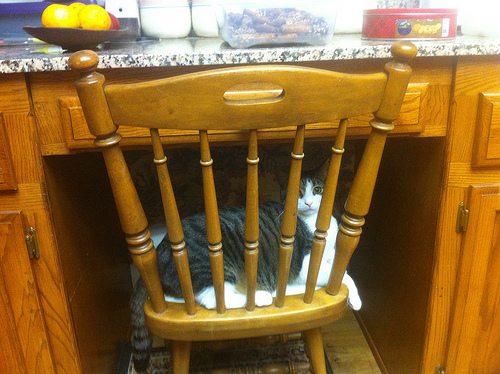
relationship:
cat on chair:
[118, 154, 363, 373] [68, 38, 418, 374]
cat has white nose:
[118, 154, 363, 373] [305, 197, 316, 208]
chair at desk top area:
[68, 38, 418, 374] [0, 32, 499, 159]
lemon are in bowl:
[42, 4, 79, 27] [20, 23, 131, 51]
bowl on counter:
[20, 23, 131, 51] [1, 5, 500, 74]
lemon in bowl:
[78, 4, 113, 32] [20, 23, 131, 51]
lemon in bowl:
[43, 1, 80, 27] [20, 23, 131, 51]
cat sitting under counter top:
[118, 154, 363, 373] [1, 5, 500, 74]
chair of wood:
[68, 38, 418, 374] [68, 40, 418, 373]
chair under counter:
[68, 38, 418, 374] [1, 5, 500, 74]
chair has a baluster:
[68, 38, 418, 374] [148, 126, 199, 316]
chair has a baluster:
[68, 38, 418, 374] [198, 129, 226, 315]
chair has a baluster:
[68, 38, 418, 374] [242, 127, 260, 311]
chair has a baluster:
[68, 38, 418, 374] [275, 125, 306, 308]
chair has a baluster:
[68, 38, 418, 374] [306, 120, 349, 304]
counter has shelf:
[1, 5, 500, 74] [0, 37, 499, 76]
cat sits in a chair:
[118, 154, 363, 373] [68, 38, 418, 374]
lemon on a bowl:
[42, 4, 79, 27] [20, 23, 131, 51]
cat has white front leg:
[118, 154, 363, 373] [337, 269, 364, 313]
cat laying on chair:
[118, 154, 363, 373] [68, 38, 418, 374]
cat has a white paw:
[118, 154, 363, 373] [337, 269, 364, 313]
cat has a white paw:
[118, 154, 363, 373] [199, 289, 275, 307]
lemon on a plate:
[78, 4, 113, 32] [20, 23, 131, 51]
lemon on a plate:
[43, 1, 80, 27] [20, 23, 131, 51]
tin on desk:
[360, 7, 459, 42] [1, 10, 499, 373]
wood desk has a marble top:
[1, 10, 499, 373] [1, 5, 500, 74]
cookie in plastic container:
[281, 22, 312, 36] [215, 4, 337, 49]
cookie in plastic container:
[257, 19, 281, 37] [215, 4, 337, 49]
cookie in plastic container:
[224, 11, 245, 32] [215, 4, 337, 49]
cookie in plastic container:
[259, 32, 297, 44] [215, 4, 337, 49]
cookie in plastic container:
[313, 17, 334, 42] [215, 4, 337, 49]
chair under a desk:
[68, 38, 418, 374] [1, 10, 499, 373]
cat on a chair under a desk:
[118, 154, 363, 373] [39, 134, 446, 373]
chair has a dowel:
[68, 38, 418, 374] [148, 126, 199, 316]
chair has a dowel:
[68, 38, 418, 374] [198, 129, 226, 315]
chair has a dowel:
[68, 38, 418, 374] [242, 127, 260, 311]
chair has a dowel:
[68, 38, 418, 374] [275, 125, 306, 308]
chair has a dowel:
[68, 38, 418, 374] [306, 120, 349, 304]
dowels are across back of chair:
[67, 40, 419, 314] [68, 41, 418, 342]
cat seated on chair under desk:
[118, 154, 363, 373] [39, 134, 446, 373]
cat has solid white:
[118, 154, 363, 373] [290, 184, 362, 311]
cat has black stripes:
[118, 154, 363, 373] [221, 217, 246, 283]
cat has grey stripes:
[118, 154, 363, 373] [189, 214, 212, 291]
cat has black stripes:
[118, 154, 363, 373] [259, 200, 278, 290]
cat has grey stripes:
[118, 154, 363, 373] [131, 285, 146, 360]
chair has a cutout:
[68, 38, 418, 374] [221, 80, 286, 108]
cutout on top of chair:
[221, 80, 286, 108] [68, 38, 418, 374]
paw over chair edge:
[337, 269, 364, 313] [143, 279, 347, 340]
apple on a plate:
[108, 9, 120, 33] [20, 23, 131, 51]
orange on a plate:
[67, 0, 88, 14] [20, 23, 131, 51]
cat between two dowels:
[118, 154, 363, 373] [275, 120, 348, 305]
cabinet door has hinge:
[439, 184, 500, 374] [454, 199, 470, 237]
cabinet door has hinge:
[439, 184, 500, 374] [433, 356, 448, 373]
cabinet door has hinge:
[0, 208, 61, 374] [20, 224, 42, 262]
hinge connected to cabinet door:
[454, 199, 470, 237] [439, 184, 500, 374]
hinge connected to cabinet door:
[433, 356, 448, 373] [439, 184, 500, 374]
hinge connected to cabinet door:
[20, 224, 42, 262] [0, 208, 61, 374]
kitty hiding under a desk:
[118, 154, 363, 373] [39, 134, 446, 373]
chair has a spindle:
[68, 38, 418, 374] [148, 126, 199, 316]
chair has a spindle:
[68, 38, 418, 374] [198, 129, 226, 315]